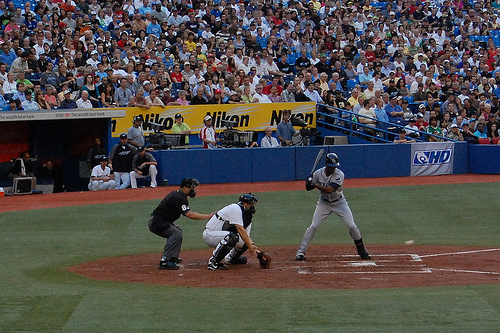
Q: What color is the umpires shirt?
A: Black.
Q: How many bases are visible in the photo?
A: 1.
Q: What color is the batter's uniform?
A: Gray.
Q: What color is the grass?
A: Green.